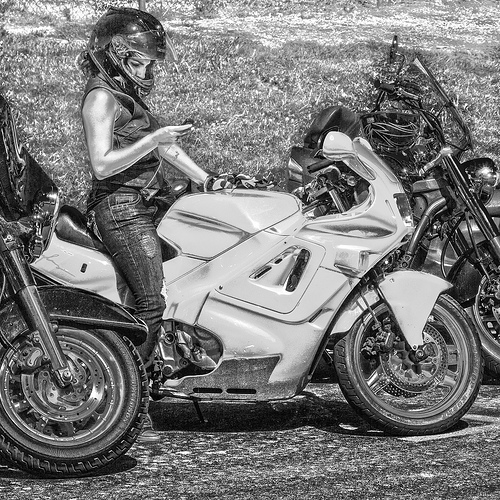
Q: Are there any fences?
A: No, there are no fences.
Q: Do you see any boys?
A: No, there are no boys.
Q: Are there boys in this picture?
A: No, there are no boys.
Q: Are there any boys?
A: No, there are no boys.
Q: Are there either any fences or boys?
A: No, there are no boys or fences.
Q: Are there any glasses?
A: No, there are no glasses.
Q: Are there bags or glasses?
A: No, there are no glasses or bags.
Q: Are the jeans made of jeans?
A: Yes, the jeans are made of jeans.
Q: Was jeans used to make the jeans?
A: Yes, the jeans are made of jeans.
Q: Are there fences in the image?
A: No, there are no fences.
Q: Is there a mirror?
A: Yes, there is a mirror.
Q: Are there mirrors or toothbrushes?
A: Yes, there is a mirror.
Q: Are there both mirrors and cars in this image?
A: No, there is a mirror but no cars.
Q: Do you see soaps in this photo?
A: No, there are no soaps.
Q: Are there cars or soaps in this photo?
A: No, there are no soaps or cars.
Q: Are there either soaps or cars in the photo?
A: No, there are no soaps or cars.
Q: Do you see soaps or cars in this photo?
A: No, there are no soaps or cars.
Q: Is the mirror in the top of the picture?
A: Yes, the mirror is in the top of the image.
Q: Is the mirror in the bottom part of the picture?
A: No, the mirror is in the top of the image.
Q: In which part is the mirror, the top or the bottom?
A: The mirror is in the top of the image.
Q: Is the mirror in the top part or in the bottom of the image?
A: The mirror is in the top of the image.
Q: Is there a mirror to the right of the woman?
A: Yes, there is a mirror to the right of the woman.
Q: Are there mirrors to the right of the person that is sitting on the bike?
A: Yes, there is a mirror to the right of the woman.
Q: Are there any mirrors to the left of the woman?
A: No, the mirror is to the right of the woman.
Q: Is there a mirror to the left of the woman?
A: No, the mirror is to the right of the woman.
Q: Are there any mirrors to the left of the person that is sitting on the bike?
A: No, the mirror is to the right of the woman.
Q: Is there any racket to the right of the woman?
A: No, there is a mirror to the right of the woman.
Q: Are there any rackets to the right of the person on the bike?
A: No, there is a mirror to the right of the woman.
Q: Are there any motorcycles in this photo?
A: Yes, there is a motorcycle.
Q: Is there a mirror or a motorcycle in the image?
A: Yes, there is a motorcycle.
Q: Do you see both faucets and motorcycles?
A: No, there is a motorcycle but no faucets.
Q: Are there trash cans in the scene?
A: No, there are no trash cans.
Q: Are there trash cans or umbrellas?
A: No, there are no trash cans or umbrellas.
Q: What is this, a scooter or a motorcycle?
A: This is a motorcycle.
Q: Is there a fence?
A: No, there are no fences.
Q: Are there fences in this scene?
A: No, there are no fences.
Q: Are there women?
A: Yes, there is a woman.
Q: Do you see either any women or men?
A: Yes, there is a woman.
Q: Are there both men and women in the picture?
A: No, there is a woman but no men.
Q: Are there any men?
A: No, there are no men.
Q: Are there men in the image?
A: No, there are no men.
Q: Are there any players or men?
A: No, there are no men or players.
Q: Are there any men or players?
A: No, there are no men or players.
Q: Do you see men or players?
A: No, there are no men or players.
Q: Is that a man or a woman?
A: That is a woman.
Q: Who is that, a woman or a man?
A: That is a woman.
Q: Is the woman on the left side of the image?
A: Yes, the woman is on the left of the image.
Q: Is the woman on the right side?
A: No, the woman is on the left of the image.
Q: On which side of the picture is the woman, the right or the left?
A: The woman is on the left of the image.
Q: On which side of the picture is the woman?
A: The woman is on the left of the image.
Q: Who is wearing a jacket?
A: The woman is wearing a jacket.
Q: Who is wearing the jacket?
A: The woman is wearing a jacket.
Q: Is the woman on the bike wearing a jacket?
A: Yes, the woman is wearing a jacket.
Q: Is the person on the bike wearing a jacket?
A: Yes, the woman is wearing a jacket.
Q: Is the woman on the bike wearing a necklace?
A: No, the woman is wearing a jacket.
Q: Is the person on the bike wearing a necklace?
A: No, the woman is wearing a jacket.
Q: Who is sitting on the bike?
A: The woman is sitting on the bike.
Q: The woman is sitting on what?
A: The woman is sitting on the bike.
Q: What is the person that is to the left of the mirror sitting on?
A: The woman is sitting on the bike.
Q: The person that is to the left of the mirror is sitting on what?
A: The woman is sitting on the bike.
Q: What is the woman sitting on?
A: The woman is sitting on the bike.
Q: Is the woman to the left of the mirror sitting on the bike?
A: Yes, the woman is sitting on the bike.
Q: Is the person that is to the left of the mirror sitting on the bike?
A: Yes, the woman is sitting on the bike.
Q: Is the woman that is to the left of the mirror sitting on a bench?
A: No, the woman is sitting on the bike.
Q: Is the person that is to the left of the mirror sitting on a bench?
A: No, the woman is sitting on the bike.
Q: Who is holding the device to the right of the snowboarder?
A: The woman is holding the cell phone.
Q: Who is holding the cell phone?
A: The woman is holding the cell phone.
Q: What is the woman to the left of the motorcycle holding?
A: The woman is holding the cell phone.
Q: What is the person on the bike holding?
A: The woman is holding the cell phone.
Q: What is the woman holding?
A: The woman is holding the cell phone.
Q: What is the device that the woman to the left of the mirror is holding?
A: The device is a cell phone.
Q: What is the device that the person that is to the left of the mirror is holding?
A: The device is a cell phone.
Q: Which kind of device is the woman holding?
A: The woman is holding the cellphone.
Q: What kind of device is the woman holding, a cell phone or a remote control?
A: The woman is holding a cell phone.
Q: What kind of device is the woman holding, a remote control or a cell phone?
A: The woman is holding a cell phone.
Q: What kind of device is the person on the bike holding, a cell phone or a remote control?
A: The woman is holding a cell phone.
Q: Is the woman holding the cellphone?
A: Yes, the woman is holding the cellphone.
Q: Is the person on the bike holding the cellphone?
A: Yes, the woman is holding the cellphone.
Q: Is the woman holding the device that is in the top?
A: Yes, the woman is holding the cellphone.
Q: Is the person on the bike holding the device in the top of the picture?
A: Yes, the woman is holding the cellphone.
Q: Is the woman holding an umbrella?
A: No, the woman is holding the cellphone.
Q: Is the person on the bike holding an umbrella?
A: No, the woman is holding the cellphone.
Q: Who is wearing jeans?
A: The woman is wearing jeans.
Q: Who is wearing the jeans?
A: The woman is wearing jeans.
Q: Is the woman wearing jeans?
A: Yes, the woman is wearing jeans.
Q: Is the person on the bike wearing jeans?
A: Yes, the woman is wearing jeans.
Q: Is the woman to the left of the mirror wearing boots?
A: No, the woman is wearing jeans.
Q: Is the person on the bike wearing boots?
A: No, the woman is wearing jeans.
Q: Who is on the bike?
A: The woman is on the bike.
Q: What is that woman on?
A: The woman is on the bike.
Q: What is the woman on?
A: The woman is on the bike.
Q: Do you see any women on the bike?
A: Yes, there is a woman on the bike.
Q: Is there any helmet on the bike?
A: No, there is a woman on the bike.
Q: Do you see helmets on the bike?
A: No, there is a woman on the bike.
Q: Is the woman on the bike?
A: Yes, the woman is on the bike.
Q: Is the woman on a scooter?
A: No, the woman is on the bike.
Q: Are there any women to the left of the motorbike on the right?
A: Yes, there is a woman to the left of the motorcycle.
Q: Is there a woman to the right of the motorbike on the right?
A: No, the woman is to the left of the motorbike.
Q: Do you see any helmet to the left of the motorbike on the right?
A: No, there is a woman to the left of the motorbike.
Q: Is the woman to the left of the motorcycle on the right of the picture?
A: Yes, the woman is to the left of the motorbike.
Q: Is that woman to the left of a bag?
A: No, the woman is to the left of the motorbike.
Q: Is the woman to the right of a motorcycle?
A: No, the woman is to the left of a motorcycle.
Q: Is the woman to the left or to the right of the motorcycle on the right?
A: The woman is to the left of the motorcycle.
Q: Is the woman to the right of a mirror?
A: No, the woman is to the left of a mirror.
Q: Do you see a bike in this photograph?
A: Yes, there is a bike.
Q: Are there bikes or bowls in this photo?
A: Yes, there is a bike.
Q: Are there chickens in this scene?
A: No, there are no chickens.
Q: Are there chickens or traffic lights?
A: No, there are no chickens or traffic lights.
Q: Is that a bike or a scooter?
A: That is a bike.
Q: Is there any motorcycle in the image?
A: Yes, there is a motorcycle.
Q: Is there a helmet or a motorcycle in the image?
A: Yes, there is a motorcycle.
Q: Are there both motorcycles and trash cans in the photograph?
A: No, there is a motorcycle but no trash cans.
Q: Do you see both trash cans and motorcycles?
A: No, there is a motorcycle but no trash cans.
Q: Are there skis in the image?
A: No, there are no skis.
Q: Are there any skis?
A: No, there are no skis.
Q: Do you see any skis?
A: No, there are no skis.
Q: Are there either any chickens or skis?
A: No, there are no skis or chickens.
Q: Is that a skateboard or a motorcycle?
A: That is a motorcycle.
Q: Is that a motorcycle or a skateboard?
A: That is a motorcycle.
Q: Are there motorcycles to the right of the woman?
A: Yes, there is a motorcycle to the right of the woman.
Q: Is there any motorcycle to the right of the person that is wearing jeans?
A: Yes, there is a motorcycle to the right of the woman.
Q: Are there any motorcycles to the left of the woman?
A: No, the motorcycle is to the right of the woman.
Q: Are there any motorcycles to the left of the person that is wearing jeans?
A: No, the motorcycle is to the right of the woman.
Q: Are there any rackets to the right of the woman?
A: No, there is a motorcycle to the right of the woman.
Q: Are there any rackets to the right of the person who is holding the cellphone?
A: No, there is a motorcycle to the right of the woman.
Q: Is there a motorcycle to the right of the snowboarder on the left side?
A: Yes, there is a motorcycle to the right of the snowboarder.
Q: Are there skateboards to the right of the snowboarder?
A: No, there is a motorcycle to the right of the snowboarder.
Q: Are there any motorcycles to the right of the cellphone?
A: Yes, there is a motorcycle to the right of the cellphone.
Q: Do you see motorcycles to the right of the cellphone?
A: Yes, there is a motorcycle to the right of the cellphone.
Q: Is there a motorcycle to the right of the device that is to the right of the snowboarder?
A: Yes, there is a motorcycle to the right of the cellphone.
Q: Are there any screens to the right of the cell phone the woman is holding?
A: No, there is a motorcycle to the right of the cellphone.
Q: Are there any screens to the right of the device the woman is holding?
A: No, there is a motorcycle to the right of the cellphone.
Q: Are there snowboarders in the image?
A: Yes, there is a snowboarder.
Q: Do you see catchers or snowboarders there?
A: Yes, there is a snowboarder.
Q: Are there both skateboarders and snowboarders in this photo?
A: No, there is a snowboarder but no skateboarders.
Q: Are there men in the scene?
A: No, there are no men.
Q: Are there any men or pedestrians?
A: No, there are no men or pedestrians.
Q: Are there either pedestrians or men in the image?
A: No, there are no men or pedestrians.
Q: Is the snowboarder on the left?
A: Yes, the snowboarder is on the left of the image.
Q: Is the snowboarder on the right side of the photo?
A: No, the snowboarder is on the left of the image.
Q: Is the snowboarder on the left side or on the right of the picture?
A: The snowboarder is on the left of the image.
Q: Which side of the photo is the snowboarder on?
A: The snowboarder is on the left of the image.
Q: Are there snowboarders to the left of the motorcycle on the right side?
A: Yes, there is a snowboarder to the left of the motorbike.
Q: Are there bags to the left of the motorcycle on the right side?
A: No, there is a snowboarder to the left of the motorcycle.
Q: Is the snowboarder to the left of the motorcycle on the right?
A: Yes, the snowboarder is to the left of the motorbike.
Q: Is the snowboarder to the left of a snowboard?
A: No, the snowboarder is to the left of the motorbike.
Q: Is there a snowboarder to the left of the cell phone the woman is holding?
A: Yes, there is a snowboarder to the left of the cellphone.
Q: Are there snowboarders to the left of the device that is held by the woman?
A: Yes, there is a snowboarder to the left of the cellphone.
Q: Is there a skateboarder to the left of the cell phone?
A: No, there is a snowboarder to the left of the cell phone.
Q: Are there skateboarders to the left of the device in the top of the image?
A: No, there is a snowboarder to the left of the cell phone.